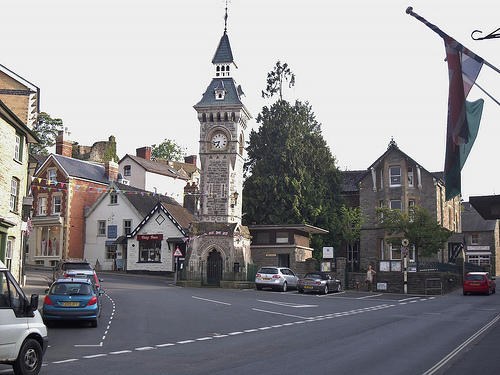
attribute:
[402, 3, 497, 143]
flag — hanging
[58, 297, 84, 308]
license — yellow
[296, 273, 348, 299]
car — silver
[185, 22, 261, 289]
clock tower — old 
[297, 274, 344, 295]
car — grey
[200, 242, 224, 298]
door — brown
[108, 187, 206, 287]
shop — old 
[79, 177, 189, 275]
white building — small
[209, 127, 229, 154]
clock — white and black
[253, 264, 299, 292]
car — silver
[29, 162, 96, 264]
building — brick, three story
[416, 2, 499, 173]
flag — rolled up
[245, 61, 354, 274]
tree — green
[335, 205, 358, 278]
tree — green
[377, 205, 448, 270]
tree — green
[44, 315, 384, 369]
lines — white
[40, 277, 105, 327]
car — parked, blue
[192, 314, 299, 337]
lines — dotted, small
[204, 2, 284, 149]
steeple — black, pointy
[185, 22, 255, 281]
tower — old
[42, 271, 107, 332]
car — blue